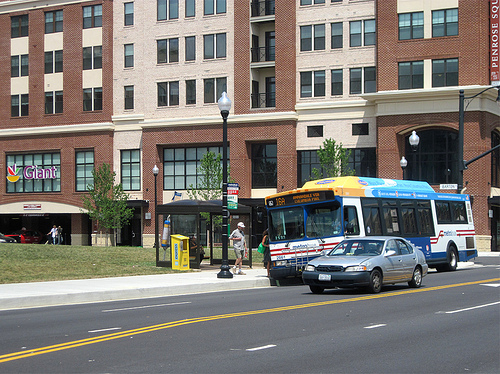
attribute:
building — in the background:
[4, 3, 482, 240]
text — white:
[474, 43, 475, 45]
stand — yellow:
[163, 226, 197, 274]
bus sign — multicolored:
[226, 179, 239, 214]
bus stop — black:
[153, 190, 266, 278]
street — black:
[10, 288, 489, 364]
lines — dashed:
[19, 291, 483, 372]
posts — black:
[146, 113, 247, 272]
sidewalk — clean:
[5, 274, 230, 302]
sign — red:
[487, 3, 499, 93]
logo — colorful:
[2, 163, 21, 189]